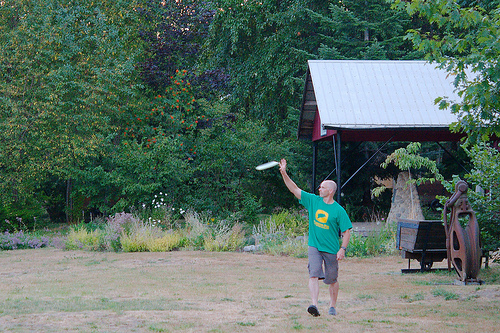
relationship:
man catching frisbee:
[278, 155, 349, 318] [256, 160, 279, 173]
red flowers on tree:
[131, 61, 204, 164] [6, 1, 253, 215]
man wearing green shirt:
[278, 155, 349, 318] [300, 190, 352, 253]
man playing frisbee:
[278, 155, 349, 318] [256, 160, 279, 173]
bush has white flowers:
[135, 199, 186, 250] [137, 193, 181, 226]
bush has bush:
[0, 211, 57, 250] [0, 217, 51, 250]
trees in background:
[6, 1, 253, 215] [2, 3, 499, 240]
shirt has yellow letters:
[300, 190, 352, 253] [311, 221, 333, 228]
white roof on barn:
[297, 58, 498, 137] [285, 50, 495, 226]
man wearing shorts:
[278, 155, 349, 318] [310, 244, 340, 284]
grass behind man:
[57, 205, 391, 257] [278, 155, 349, 318]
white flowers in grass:
[137, 193, 181, 226] [57, 205, 391, 257]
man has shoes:
[278, 155, 349, 318] [310, 303, 338, 319]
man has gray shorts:
[278, 155, 349, 318] [310, 244, 340, 284]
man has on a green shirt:
[278, 155, 349, 318] [300, 190, 352, 253]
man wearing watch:
[278, 155, 349, 318] [340, 246, 349, 251]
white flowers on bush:
[137, 193, 181, 226] [135, 199, 186, 250]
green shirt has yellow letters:
[300, 190, 352, 253] [311, 221, 333, 228]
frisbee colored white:
[256, 160, 279, 173] [255, 161, 279, 173]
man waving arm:
[278, 155, 349, 318] [281, 160, 309, 208]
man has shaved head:
[278, 155, 349, 318] [322, 180, 340, 197]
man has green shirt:
[278, 155, 349, 318] [300, 190, 352, 253]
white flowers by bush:
[137, 193, 181, 226] [135, 199, 186, 250]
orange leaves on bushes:
[128, 235, 238, 251] [72, 226, 249, 246]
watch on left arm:
[340, 246, 349, 251] [339, 211, 352, 268]